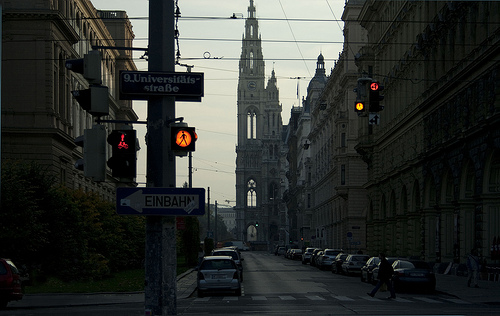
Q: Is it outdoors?
A: Yes, it is outdoors.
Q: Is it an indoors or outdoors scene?
A: It is outdoors.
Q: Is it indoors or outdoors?
A: It is outdoors.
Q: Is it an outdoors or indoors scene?
A: It is outdoors.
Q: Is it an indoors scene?
A: No, it is outdoors.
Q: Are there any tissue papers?
A: No, there are no tissue papers.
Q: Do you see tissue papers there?
A: No, there are no tissue papers.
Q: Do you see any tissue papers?
A: No, there are no tissue papers.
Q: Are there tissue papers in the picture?
A: No, there are no tissue papers.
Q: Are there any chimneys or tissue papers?
A: No, there are no tissue papers or chimneys.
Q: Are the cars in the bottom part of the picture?
A: Yes, the cars are in the bottom of the image.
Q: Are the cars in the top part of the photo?
A: No, the cars are in the bottom of the image.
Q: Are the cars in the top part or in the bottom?
A: The cars are in the bottom of the image.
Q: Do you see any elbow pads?
A: No, there are no elbow pads.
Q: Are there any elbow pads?
A: No, there are no elbow pads.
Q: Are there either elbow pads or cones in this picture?
A: No, there are no elbow pads or cones.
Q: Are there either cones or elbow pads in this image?
A: No, there are no elbow pads or cones.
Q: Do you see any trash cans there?
A: No, there are no trash cans.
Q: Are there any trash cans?
A: No, there are no trash cans.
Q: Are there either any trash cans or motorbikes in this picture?
A: No, there are no trash cans or motorbikes.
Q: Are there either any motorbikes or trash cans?
A: No, there are no trash cans or motorbikes.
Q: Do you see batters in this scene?
A: No, there are no batters.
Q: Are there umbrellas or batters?
A: No, there are no batters or umbrellas.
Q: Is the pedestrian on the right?
A: Yes, the pedestrian is on the right of the image.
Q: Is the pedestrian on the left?
A: No, the pedestrian is on the right of the image.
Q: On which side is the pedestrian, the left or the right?
A: The pedestrian is on the right of the image.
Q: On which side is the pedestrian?
A: The pedestrian is on the right of the image.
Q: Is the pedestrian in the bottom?
A: Yes, the pedestrian is in the bottom of the image.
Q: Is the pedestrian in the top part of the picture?
A: No, the pedestrian is in the bottom of the image.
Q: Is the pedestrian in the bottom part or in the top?
A: The pedestrian is in the bottom of the image.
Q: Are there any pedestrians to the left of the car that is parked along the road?
A: Yes, there is a pedestrian to the left of the car.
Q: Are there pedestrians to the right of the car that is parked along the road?
A: No, the pedestrian is to the left of the car.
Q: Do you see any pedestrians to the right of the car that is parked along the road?
A: No, the pedestrian is to the left of the car.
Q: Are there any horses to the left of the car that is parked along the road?
A: No, there is a pedestrian to the left of the car.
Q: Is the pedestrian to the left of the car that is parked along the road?
A: Yes, the pedestrian is to the left of the car.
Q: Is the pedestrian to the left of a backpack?
A: No, the pedestrian is to the left of the car.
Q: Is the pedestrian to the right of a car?
A: No, the pedestrian is to the left of a car.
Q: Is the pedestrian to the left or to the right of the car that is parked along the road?
A: The pedestrian is to the left of the car.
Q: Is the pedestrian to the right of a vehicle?
A: Yes, the pedestrian is to the right of a vehicle.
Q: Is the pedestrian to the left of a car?
A: No, the pedestrian is to the right of a car.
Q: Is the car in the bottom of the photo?
A: Yes, the car is in the bottom of the image.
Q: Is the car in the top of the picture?
A: No, the car is in the bottom of the image.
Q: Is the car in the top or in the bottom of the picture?
A: The car is in the bottom of the image.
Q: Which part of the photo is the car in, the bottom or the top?
A: The car is in the bottom of the image.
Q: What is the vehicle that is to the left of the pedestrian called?
A: The vehicle is a car.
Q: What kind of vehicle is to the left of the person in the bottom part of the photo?
A: The vehicle is a car.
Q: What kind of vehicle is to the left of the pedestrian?
A: The vehicle is a car.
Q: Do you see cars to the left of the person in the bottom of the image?
A: Yes, there is a car to the left of the pedestrian.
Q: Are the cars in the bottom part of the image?
A: Yes, the cars are in the bottom of the image.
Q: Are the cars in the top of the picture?
A: No, the cars are in the bottom of the image.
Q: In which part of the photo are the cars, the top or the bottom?
A: The cars are in the bottom of the image.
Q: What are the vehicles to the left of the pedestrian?
A: The vehicles are cars.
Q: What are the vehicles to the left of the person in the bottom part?
A: The vehicles are cars.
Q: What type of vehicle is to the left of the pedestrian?
A: The vehicles are cars.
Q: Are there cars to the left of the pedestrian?
A: Yes, there are cars to the left of the pedestrian.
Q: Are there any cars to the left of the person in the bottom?
A: Yes, there are cars to the left of the pedestrian.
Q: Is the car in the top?
A: No, the car is in the bottom of the image.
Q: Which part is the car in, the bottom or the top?
A: The car is in the bottom of the image.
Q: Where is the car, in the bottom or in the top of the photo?
A: The car is in the bottom of the image.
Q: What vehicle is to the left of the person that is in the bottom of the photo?
A: The vehicle is a car.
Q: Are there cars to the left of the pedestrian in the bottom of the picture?
A: Yes, there is a car to the left of the pedestrian.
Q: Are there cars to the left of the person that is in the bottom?
A: Yes, there is a car to the left of the pedestrian.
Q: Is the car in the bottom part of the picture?
A: Yes, the car is in the bottom of the image.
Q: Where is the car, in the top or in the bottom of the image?
A: The car is in the bottom of the image.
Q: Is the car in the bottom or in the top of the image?
A: The car is in the bottom of the image.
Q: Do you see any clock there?
A: No, there are no clocks.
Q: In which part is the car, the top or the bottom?
A: The car is in the bottom of the image.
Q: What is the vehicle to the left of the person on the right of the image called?
A: The vehicle is a car.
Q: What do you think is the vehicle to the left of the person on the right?
A: The vehicle is a car.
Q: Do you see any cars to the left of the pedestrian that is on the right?
A: Yes, there is a car to the left of the pedestrian.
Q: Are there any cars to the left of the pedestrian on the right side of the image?
A: Yes, there is a car to the left of the pedestrian.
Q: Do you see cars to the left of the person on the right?
A: Yes, there is a car to the left of the pedestrian.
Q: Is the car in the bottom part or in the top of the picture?
A: The car is in the bottom of the image.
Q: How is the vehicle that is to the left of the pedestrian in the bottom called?
A: The vehicle is a car.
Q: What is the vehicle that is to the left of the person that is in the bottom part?
A: The vehicle is a car.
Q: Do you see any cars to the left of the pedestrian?
A: Yes, there is a car to the left of the pedestrian.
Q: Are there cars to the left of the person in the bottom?
A: Yes, there is a car to the left of the pedestrian.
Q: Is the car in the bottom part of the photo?
A: Yes, the car is in the bottom of the image.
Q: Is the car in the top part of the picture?
A: No, the car is in the bottom of the image.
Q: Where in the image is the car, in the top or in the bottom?
A: The car is in the bottom of the image.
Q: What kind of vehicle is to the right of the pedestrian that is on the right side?
A: The vehicle is a car.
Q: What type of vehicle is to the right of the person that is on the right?
A: The vehicle is a car.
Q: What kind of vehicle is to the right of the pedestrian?
A: The vehicle is a car.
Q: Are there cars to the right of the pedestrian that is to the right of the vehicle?
A: Yes, there is a car to the right of the pedestrian.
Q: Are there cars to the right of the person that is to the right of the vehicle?
A: Yes, there is a car to the right of the pedestrian.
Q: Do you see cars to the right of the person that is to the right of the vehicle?
A: Yes, there is a car to the right of the pedestrian.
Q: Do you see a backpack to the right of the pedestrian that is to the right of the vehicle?
A: No, there is a car to the right of the pedestrian.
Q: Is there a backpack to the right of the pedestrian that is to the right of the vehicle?
A: No, there is a car to the right of the pedestrian.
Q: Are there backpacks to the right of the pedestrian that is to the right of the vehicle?
A: No, there is a car to the right of the pedestrian.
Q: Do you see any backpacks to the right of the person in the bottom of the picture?
A: No, there is a car to the right of the pedestrian.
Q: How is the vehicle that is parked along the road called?
A: The vehicle is a car.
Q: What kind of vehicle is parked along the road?
A: The vehicle is a car.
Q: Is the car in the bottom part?
A: Yes, the car is in the bottom of the image.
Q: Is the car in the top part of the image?
A: No, the car is in the bottom of the image.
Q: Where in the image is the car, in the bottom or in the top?
A: The car is in the bottom of the image.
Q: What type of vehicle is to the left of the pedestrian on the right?
A: The vehicle is a car.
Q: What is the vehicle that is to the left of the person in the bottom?
A: The vehicle is a car.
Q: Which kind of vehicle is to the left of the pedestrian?
A: The vehicle is a car.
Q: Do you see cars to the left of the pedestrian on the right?
A: Yes, there is a car to the left of the pedestrian.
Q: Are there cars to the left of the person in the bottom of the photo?
A: Yes, there is a car to the left of the pedestrian.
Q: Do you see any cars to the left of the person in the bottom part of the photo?
A: Yes, there is a car to the left of the pedestrian.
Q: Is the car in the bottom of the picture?
A: Yes, the car is in the bottom of the image.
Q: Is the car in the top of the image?
A: No, the car is in the bottom of the image.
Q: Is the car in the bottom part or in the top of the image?
A: The car is in the bottom of the image.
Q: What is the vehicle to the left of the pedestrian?
A: The vehicle is a car.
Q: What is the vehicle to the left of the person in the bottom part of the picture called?
A: The vehicle is a car.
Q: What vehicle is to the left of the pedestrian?
A: The vehicle is a car.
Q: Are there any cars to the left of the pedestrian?
A: Yes, there is a car to the left of the pedestrian.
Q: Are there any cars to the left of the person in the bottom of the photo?
A: Yes, there is a car to the left of the pedestrian.